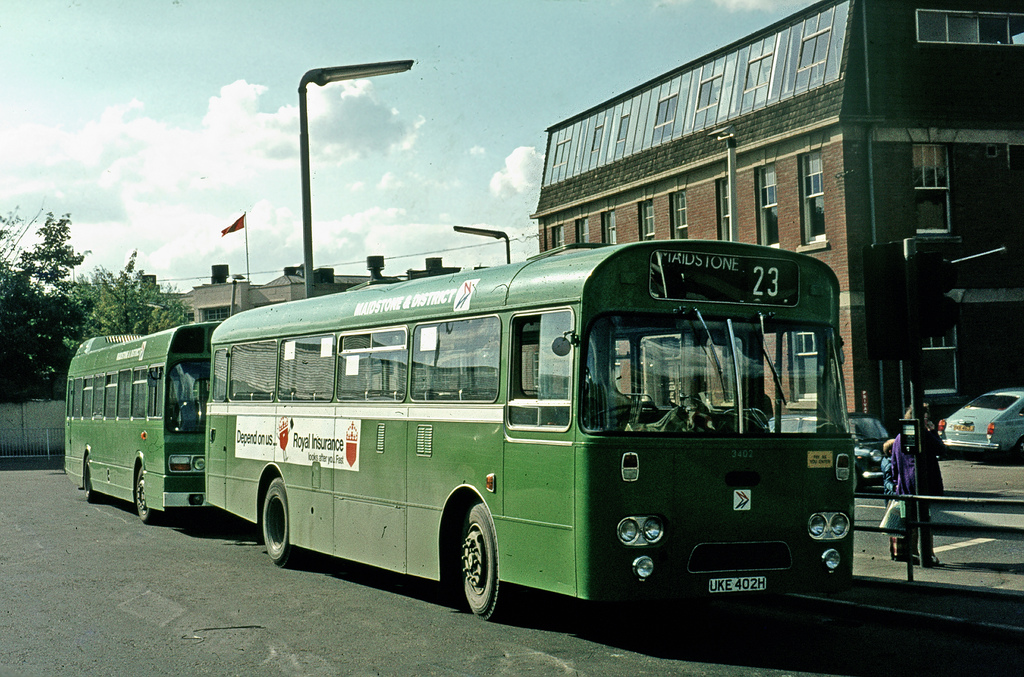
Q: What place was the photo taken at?
A: It was taken at the road.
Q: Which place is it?
A: It is a road.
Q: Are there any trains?
A: No, there are no trains.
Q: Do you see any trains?
A: No, there are no trains.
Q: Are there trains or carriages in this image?
A: No, there are no trains or carriages.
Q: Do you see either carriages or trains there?
A: No, there are no trains or carriages.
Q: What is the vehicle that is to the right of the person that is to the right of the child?
A: The vehicle is a car.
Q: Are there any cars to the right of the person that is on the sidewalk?
A: Yes, there is a car to the right of the person.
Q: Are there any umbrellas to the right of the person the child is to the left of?
A: No, there is a car to the right of the person.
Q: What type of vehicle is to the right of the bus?
A: The vehicle is a car.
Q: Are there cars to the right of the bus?
A: Yes, there is a car to the right of the bus.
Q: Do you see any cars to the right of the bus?
A: Yes, there is a car to the right of the bus.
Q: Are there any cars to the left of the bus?
A: No, the car is to the right of the bus.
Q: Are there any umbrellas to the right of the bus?
A: No, there is a car to the right of the bus.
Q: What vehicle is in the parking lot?
A: The vehicle is a car.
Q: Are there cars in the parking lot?
A: Yes, there is a car in the parking lot.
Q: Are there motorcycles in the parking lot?
A: No, there is a car in the parking lot.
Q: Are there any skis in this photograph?
A: No, there are no skis.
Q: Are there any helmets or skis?
A: No, there are no skis or helmets.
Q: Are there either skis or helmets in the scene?
A: No, there are no skis or helmets.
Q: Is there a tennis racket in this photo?
A: No, there are no rackets.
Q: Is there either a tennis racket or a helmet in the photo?
A: No, there are no rackets or helmets.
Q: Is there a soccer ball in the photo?
A: No, there are no soccer balls.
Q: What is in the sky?
A: The clouds are in the sky.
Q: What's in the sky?
A: The clouds are in the sky.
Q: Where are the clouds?
A: The clouds are in the sky.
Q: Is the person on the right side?
A: Yes, the person is on the right of the image.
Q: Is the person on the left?
A: No, the person is on the right of the image.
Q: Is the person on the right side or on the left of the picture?
A: The person is on the right of the image.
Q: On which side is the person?
A: The person is on the right of the image.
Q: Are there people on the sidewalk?
A: Yes, there is a person on the sidewalk.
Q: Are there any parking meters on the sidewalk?
A: No, there is a person on the sidewalk.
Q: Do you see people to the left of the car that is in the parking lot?
A: Yes, there is a person to the left of the car.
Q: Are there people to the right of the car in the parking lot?
A: No, the person is to the left of the car.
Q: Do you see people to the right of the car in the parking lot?
A: No, the person is to the left of the car.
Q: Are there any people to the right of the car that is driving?
A: Yes, there is a person to the right of the car.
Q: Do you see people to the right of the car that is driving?
A: Yes, there is a person to the right of the car.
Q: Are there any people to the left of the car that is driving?
A: No, the person is to the right of the car.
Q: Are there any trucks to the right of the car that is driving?
A: No, there is a person to the right of the car.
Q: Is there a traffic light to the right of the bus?
A: No, there is a person to the right of the bus.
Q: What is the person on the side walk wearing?
A: The person is wearing a jacket.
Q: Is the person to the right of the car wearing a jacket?
A: Yes, the person is wearing a jacket.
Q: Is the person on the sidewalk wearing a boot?
A: No, the person is wearing a jacket.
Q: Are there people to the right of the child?
A: Yes, there is a person to the right of the child.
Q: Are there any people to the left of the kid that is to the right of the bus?
A: No, the person is to the right of the child.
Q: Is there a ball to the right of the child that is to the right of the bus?
A: No, there is a person to the right of the child.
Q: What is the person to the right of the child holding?
A: The person is holding the bag.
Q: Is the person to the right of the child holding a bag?
A: Yes, the person is holding a bag.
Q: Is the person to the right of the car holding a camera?
A: No, the person is holding a bag.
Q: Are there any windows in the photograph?
A: Yes, there are windows.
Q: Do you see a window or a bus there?
A: Yes, there are windows.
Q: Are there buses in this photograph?
A: Yes, there is a bus.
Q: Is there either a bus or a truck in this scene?
A: Yes, there is a bus.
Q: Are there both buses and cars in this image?
A: Yes, there are both a bus and a car.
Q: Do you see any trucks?
A: No, there are no trucks.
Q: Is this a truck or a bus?
A: This is a bus.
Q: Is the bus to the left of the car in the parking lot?
A: Yes, the bus is to the left of the car.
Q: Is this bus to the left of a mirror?
A: No, the bus is to the left of the car.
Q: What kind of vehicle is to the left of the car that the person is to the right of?
A: The vehicle is a bus.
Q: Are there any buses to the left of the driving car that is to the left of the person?
A: Yes, there is a bus to the left of the car.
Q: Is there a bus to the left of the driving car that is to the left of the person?
A: Yes, there is a bus to the left of the car.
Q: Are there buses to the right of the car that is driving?
A: No, the bus is to the left of the car.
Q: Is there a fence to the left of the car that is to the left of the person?
A: No, there is a bus to the left of the car.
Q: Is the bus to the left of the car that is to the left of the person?
A: Yes, the bus is to the left of the car.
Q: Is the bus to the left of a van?
A: No, the bus is to the left of the car.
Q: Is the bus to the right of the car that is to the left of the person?
A: No, the bus is to the left of the car.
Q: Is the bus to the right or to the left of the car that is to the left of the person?
A: The bus is to the left of the car.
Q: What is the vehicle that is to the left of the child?
A: The vehicle is a bus.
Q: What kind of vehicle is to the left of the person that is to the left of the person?
A: The vehicle is a bus.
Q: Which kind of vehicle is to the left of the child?
A: The vehicle is a bus.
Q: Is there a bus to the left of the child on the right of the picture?
A: Yes, there is a bus to the left of the kid.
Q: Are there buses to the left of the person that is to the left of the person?
A: Yes, there is a bus to the left of the kid.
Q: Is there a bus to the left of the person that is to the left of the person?
A: Yes, there is a bus to the left of the kid.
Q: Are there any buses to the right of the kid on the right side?
A: No, the bus is to the left of the kid.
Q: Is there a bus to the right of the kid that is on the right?
A: No, the bus is to the left of the kid.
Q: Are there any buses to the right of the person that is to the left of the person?
A: No, the bus is to the left of the kid.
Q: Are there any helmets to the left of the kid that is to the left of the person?
A: No, there is a bus to the left of the child.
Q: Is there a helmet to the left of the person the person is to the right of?
A: No, there is a bus to the left of the child.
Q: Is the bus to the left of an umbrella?
A: No, the bus is to the left of the child.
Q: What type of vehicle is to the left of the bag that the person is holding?
A: The vehicle is a bus.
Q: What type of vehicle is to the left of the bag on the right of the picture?
A: The vehicle is a bus.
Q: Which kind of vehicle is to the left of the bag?
A: The vehicle is a bus.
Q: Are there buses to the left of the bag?
A: Yes, there is a bus to the left of the bag.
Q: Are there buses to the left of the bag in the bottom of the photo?
A: Yes, there is a bus to the left of the bag.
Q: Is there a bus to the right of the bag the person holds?
A: No, the bus is to the left of the bag.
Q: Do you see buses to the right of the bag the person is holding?
A: No, the bus is to the left of the bag.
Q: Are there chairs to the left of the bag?
A: No, there is a bus to the left of the bag.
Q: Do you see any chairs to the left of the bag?
A: No, there is a bus to the left of the bag.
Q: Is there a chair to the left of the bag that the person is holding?
A: No, there is a bus to the left of the bag.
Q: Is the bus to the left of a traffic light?
A: No, the bus is to the left of the bag.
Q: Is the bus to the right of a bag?
A: No, the bus is to the left of a bag.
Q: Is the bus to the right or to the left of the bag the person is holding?
A: The bus is to the left of the bag.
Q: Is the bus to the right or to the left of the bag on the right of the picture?
A: The bus is to the left of the bag.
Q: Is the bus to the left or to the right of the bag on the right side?
A: The bus is to the left of the bag.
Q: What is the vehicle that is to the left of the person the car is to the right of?
A: The vehicle is a bus.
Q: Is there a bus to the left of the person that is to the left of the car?
A: Yes, there is a bus to the left of the person.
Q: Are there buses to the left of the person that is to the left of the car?
A: Yes, there is a bus to the left of the person.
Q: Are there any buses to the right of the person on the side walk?
A: No, the bus is to the left of the person.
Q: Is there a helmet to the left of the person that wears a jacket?
A: No, there is a bus to the left of the person.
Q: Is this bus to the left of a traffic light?
A: No, the bus is to the left of the person.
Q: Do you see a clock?
A: No, there are no clocks.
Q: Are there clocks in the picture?
A: No, there are no clocks.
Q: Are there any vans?
A: No, there are no vans.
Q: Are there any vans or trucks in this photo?
A: No, there are no vans or trucks.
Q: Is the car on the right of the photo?
A: Yes, the car is on the right of the image.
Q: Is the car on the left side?
A: No, the car is on the right of the image.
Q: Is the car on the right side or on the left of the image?
A: The car is on the right of the image.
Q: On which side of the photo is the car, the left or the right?
A: The car is on the right of the image.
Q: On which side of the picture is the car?
A: The car is on the right of the image.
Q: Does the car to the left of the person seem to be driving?
A: Yes, the car is driving.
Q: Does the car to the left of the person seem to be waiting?
A: No, the car is driving.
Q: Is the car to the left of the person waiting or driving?
A: The car is driving.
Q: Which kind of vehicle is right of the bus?
A: The vehicle is a car.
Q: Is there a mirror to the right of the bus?
A: No, there is a car to the right of the bus.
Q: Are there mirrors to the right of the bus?
A: No, there is a car to the right of the bus.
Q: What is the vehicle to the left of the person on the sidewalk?
A: The vehicle is a car.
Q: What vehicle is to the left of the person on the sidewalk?
A: The vehicle is a car.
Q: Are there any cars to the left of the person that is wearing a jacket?
A: Yes, there is a car to the left of the person.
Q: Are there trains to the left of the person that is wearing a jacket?
A: No, there is a car to the left of the person.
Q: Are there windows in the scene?
A: Yes, there is a window.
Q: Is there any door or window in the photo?
A: Yes, there is a window.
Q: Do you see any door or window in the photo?
A: Yes, there is a window.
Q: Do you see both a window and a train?
A: No, there is a window but no trains.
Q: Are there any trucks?
A: No, there are no trucks.